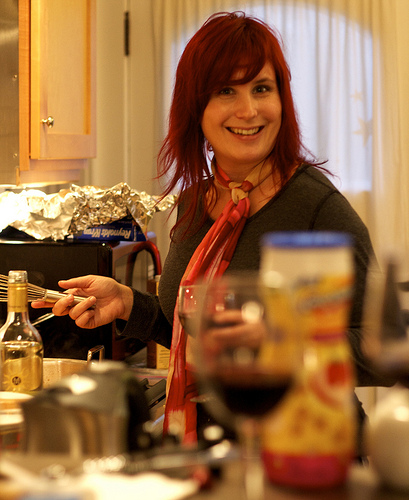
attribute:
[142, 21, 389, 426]
woman — smiling, happy, here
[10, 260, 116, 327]
whisk — steel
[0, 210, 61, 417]
oil — extra virgin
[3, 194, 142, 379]
oven — black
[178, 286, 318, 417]
wine — red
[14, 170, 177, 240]
wrap — crumpled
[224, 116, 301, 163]
teeth — white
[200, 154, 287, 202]
scarf — colorful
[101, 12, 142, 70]
hinge — black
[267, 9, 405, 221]
curtain — here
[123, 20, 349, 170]
hair — auburn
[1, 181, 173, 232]
foil — crumpled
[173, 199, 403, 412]
top — green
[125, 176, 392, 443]
shirt — dark